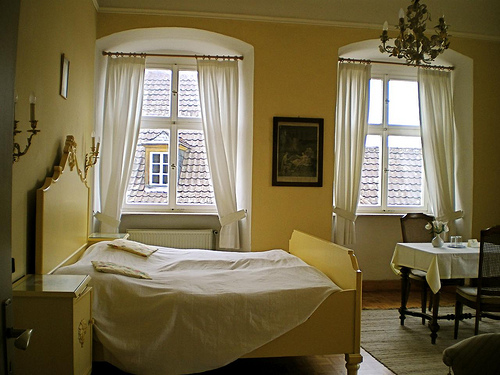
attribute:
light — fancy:
[83, 130, 103, 178]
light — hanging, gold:
[376, 1, 452, 69]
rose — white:
[424, 221, 434, 233]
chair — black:
[398, 212, 462, 340]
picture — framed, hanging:
[269, 114, 326, 188]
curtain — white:
[332, 55, 373, 254]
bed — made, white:
[32, 132, 365, 375]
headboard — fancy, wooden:
[32, 132, 90, 276]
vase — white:
[431, 230, 446, 249]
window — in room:
[347, 70, 453, 210]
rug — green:
[356, 305, 498, 373]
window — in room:
[106, 61, 235, 212]